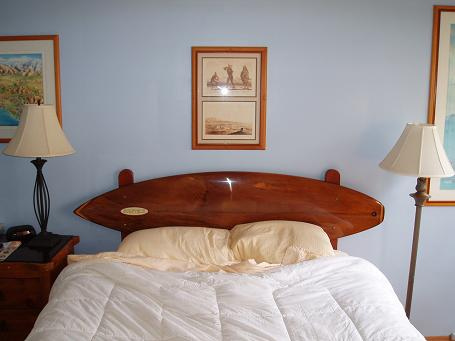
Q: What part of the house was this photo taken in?
A: Bedroom.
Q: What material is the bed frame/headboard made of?
A: Wood.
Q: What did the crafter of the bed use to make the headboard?
A: Surfboard.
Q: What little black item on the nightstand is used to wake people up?
A: Alarm clock.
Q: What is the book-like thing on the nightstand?
A: Magazine.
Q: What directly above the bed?
A: Picture.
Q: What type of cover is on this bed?
A: Down comforter.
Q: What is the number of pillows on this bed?
A: 2.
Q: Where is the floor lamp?
A: Right of the bed.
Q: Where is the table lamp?
A: Left of the bed.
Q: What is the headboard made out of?
A: Wood.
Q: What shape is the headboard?
A: Shaped like a surfboard.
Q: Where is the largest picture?
A: On the wall to the right.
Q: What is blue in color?
A: The wall.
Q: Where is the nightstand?
A: Left of the bed.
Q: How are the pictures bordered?
A: With brown picture frames.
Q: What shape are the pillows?
A: Rectangle.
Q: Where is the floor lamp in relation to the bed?
A: On the right.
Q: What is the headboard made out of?
A: Wood.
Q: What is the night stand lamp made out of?
A: Metal.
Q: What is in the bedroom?
A: Bed.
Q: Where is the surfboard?
A: Head board.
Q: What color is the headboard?
A: Brown.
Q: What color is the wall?
A: Blue.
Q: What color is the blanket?
A: White.